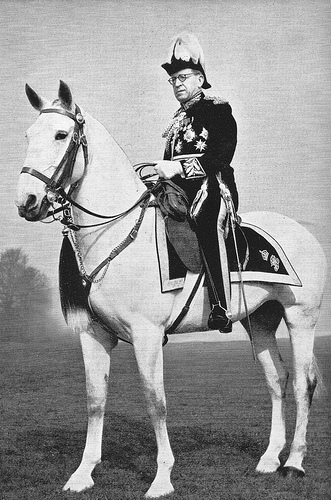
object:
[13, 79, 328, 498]
horse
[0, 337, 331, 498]
grass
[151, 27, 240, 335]
man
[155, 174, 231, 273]
saddle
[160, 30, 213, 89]
cap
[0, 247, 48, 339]
tree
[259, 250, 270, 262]
emblem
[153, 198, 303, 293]
blanket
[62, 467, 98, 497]
hoof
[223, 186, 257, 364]
saber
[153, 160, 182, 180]
hand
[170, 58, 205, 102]
head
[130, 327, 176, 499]
leg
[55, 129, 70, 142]
eye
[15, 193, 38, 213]
nose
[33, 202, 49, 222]
mouth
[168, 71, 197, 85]
glasses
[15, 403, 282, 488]
shadow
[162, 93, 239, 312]
uniform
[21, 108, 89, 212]
bridal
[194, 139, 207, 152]
star